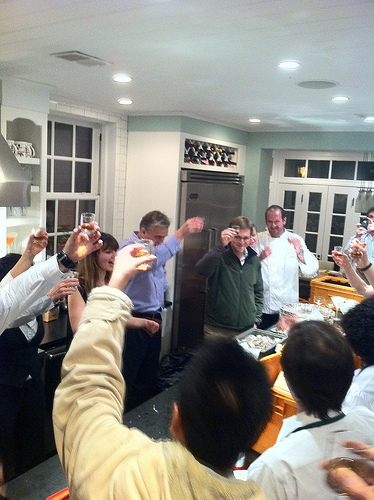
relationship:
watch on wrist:
[55, 250, 77, 271] [55, 249, 79, 271]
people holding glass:
[0, 204, 374, 499] [194, 210, 210, 222]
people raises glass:
[0, 204, 374, 499] [130, 236, 157, 270]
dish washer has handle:
[44, 345, 69, 457] [46, 349, 67, 355]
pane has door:
[307, 190, 323, 213] [242, 140, 353, 261]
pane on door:
[332, 192, 349, 216] [319, 177, 372, 291]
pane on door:
[182, 178, 209, 339] [172, 157, 259, 353]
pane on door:
[326, 188, 356, 218] [317, 180, 372, 296]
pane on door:
[323, 213, 348, 237] [317, 180, 372, 296]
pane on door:
[322, 232, 348, 265] [317, 180, 372, 296]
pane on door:
[306, 213, 320, 234] [271, 181, 330, 261]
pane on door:
[283, 190, 295, 209] [278, 184, 328, 257]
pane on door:
[282, 211, 292, 227] [278, 184, 328, 257]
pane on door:
[307, 190, 320, 211] [278, 184, 328, 257]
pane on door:
[306, 213, 318, 229] [325, 185, 360, 271]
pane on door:
[305, 231, 317, 251] [325, 185, 360, 271]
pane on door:
[70, 129, 91, 161] [46, 109, 109, 247]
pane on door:
[54, 122, 72, 156] [47, 112, 109, 258]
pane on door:
[72, 159, 94, 200] [38, 111, 108, 258]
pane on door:
[57, 198, 78, 232] [42, 112, 113, 256]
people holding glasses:
[6, 169, 367, 498] [27, 203, 226, 282]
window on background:
[49, 112, 100, 204] [9, 87, 136, 261]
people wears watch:
[0, 204, 374, 499] [56, 249, 79, 269]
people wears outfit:
[0, 204, 374, 499] [252, 230, 318, 322]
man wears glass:
[0, 205, 374, 500] [229, 220, 242, 235]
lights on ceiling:
[112, 61, 374, 125] [1, 2, 371, 132]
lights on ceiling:
[247, 119, 260, 122] [1, 2, 371, 132]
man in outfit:
[249, 205, 318, 330] [252, 228, 319, 330]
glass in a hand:
[134, 238, 160, 273] [105, 242, 154, 284]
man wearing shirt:
[0, 205, 374, 500] [116, 228, 181, 310]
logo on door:
[187, 191, 198, 200] [179, 182, 241, 289]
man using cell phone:
[0, 205, 374, 500] [358, 211, 369, 233]